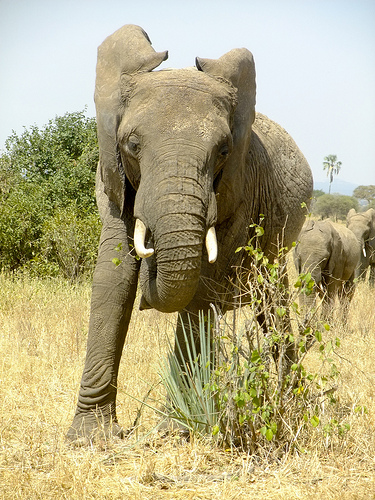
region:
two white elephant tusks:
[110, 198, 247, 293]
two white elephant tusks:
[69, 165, 217, 294]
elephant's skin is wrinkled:
[72, 214, 135, 437]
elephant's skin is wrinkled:
[146, 189, 197, 325]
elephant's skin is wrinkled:
[211, 136, 289, 286]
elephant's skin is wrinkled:
[28, 180, 218, 360]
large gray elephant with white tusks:
[67, 21, 317, 430]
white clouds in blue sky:
[13, 16, 39, 52]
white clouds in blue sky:
[27, 70, 55, 101]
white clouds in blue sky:
[153, 5, 190, 29]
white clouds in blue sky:
[232, 6, 285, 40]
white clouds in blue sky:
[281, 22, 322, 78]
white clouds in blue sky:
[300, 45, 353, 81]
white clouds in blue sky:
[304, 87, 349, 111]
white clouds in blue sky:
[21, 33, 64, 57]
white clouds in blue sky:
[33, 30, 67, 86]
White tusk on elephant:
[198, 213, 222, 268]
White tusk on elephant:
[127, 208, 155, 278]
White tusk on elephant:
[361, 243, 371, 258]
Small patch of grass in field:
[15, 457, 29, 486]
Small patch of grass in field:
[52, 455, 137, 489]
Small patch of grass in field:
[141, 308, 257, 459]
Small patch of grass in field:
[232, 213, 335, 487]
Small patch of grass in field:
[322, 457, 364, 497]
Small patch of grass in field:
[343, 381, 373, 423]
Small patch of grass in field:
[15, 281, 53, 342]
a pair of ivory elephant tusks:
[131, 219, 222, 264]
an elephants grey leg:
[70, 225, 133, 444]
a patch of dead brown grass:
[0, 451, 373, 499]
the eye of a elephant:
[128, 138, 139, 151]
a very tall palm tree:
[321, 153, 341, 196]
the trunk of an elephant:
[138, 201, 209, 312]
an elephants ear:
[90, 22, 169, 215]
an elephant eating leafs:
[68, 22, 312, 458]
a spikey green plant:
[158, 306, 224, 434]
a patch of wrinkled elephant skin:
[76, 363, 117, 417]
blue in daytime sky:
[0, 1, 374, 182]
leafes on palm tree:
[320, 152, 343, 190]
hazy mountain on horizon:
[317, 176, 360, 196]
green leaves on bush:
[4, 114, 96, 271]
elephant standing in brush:
[70, 22, 297, 443]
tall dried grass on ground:
[0, 260, 372, 497]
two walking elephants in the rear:
[296, 209, 371, 310]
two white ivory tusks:
[134, 218, 219, 260]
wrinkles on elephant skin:
[243, 144, 297, 253]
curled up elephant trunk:
[137, 229, 212, 313]